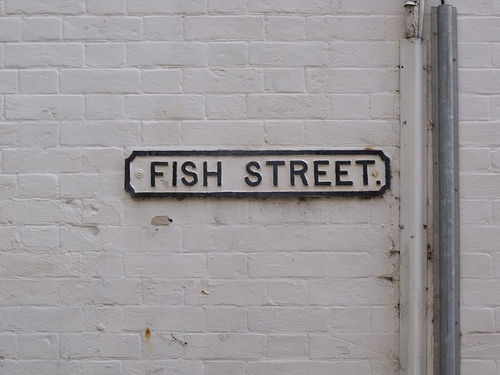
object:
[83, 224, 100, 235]
peeling paint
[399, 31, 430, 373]
pipe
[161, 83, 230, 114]
brown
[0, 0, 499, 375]
bricked wall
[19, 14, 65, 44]
brick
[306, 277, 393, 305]
brick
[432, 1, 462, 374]
pipe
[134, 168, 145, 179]
white screw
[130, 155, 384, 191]
white sign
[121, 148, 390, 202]
black border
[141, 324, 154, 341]
spot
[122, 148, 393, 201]
border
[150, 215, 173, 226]
chip